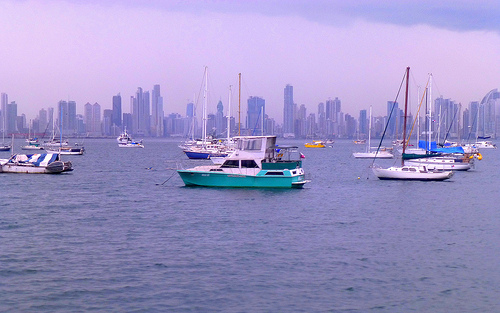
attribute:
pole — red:
[398, 66, 412, 165]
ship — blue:
[176, 154, 310, 196]